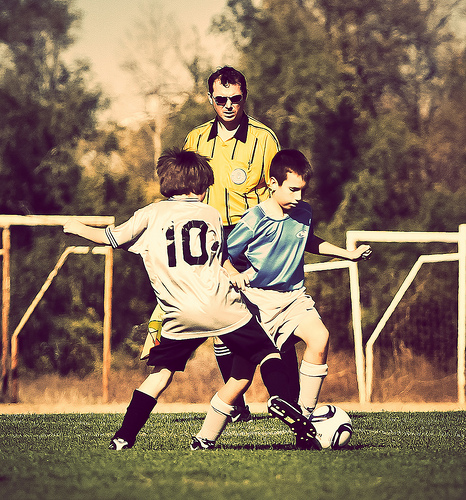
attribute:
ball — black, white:
[307, 404, 353, 449]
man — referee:
[179, 67, 299, 423]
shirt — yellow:
[183, 66, 281, 226]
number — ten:
[163, 219, 209, 268]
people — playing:
[63, 66, 373, 452]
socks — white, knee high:
[197, 393, 237, 442]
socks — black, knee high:
[113, 388, 157, 442]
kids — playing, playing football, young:
[62, 147, 372, 449]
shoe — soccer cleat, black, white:
[266, 395, 318, 442]